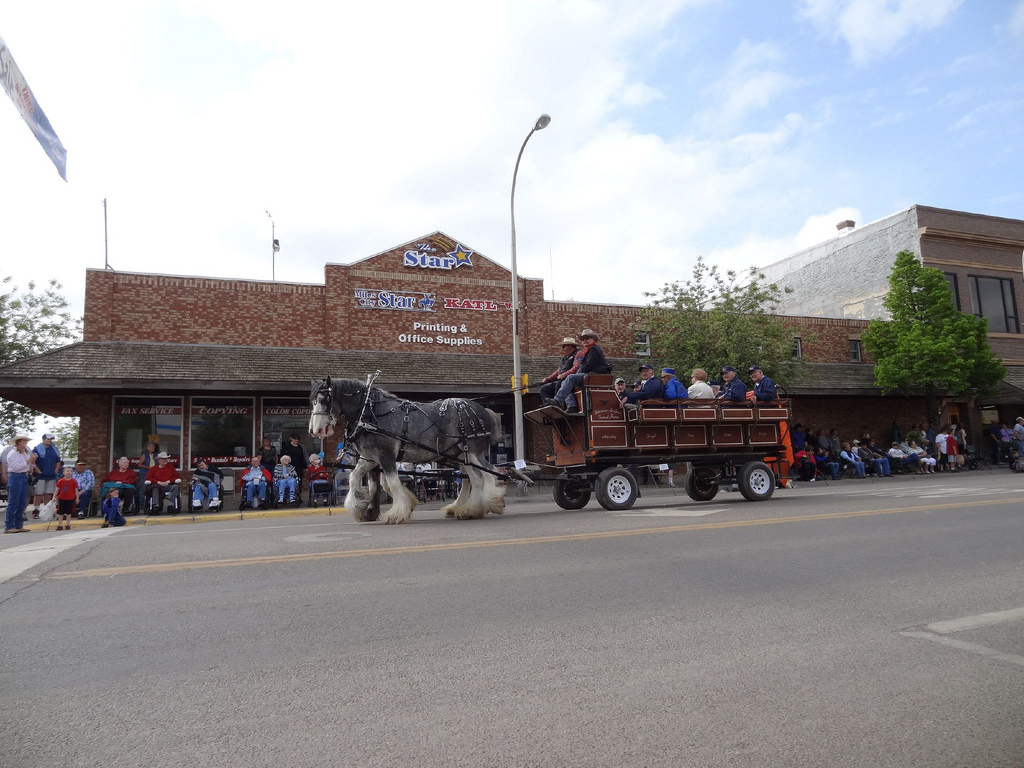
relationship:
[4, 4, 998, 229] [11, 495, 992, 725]
sky above land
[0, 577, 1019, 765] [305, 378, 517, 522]
land next to horse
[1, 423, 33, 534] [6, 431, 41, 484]
person wearing shirt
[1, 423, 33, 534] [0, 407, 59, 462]
person wearing cowboy hat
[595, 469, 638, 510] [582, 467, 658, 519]
tire on tire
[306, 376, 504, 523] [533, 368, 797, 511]
horse in front of carriage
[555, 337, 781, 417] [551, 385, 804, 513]
people in carriage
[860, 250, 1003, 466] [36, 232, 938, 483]
tree next to building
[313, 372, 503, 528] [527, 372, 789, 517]
horse pulling wagon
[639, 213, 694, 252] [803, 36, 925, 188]
clouds in sky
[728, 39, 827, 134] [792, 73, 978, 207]
clouds in sky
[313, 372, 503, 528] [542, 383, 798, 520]
horse pulling wagon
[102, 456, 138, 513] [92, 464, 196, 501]
people in shirt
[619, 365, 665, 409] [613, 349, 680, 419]
people in shirt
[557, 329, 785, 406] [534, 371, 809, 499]
people in wagon